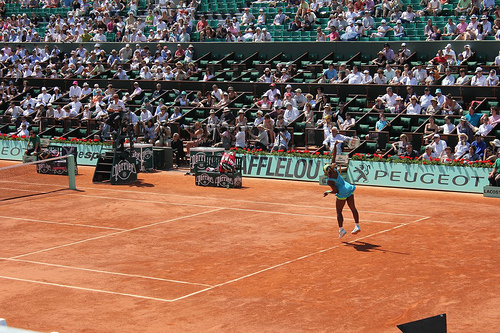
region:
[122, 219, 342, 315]
this is the playing ground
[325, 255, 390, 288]
the ground is brown in color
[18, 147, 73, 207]
this is the net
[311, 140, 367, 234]
this is a lady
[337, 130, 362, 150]
this is the racket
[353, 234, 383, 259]
this is a shadow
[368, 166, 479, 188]
this is a writing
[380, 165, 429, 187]
the writingtis is black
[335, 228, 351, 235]
this is a shoe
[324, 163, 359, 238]
tennis player in blue shirt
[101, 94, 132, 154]
referee sitting on green stand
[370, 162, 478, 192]
green sign with black letters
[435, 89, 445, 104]
man in green hat watching game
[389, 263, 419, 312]
footprints on red tennis court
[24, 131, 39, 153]
ball boy in green sitting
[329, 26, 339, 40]
man in red watching game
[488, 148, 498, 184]
guy in green sitting at side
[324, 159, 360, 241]
tennis player jumping hitting ball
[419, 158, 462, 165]
red roses on wall at side of court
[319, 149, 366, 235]
this is a tennis player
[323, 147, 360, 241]
the player is swinging the racket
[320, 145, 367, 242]
the player is on air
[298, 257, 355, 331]
the pitch is brown in color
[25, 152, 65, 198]
this is a net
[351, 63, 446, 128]
these are the spectators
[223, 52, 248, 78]
the seats are empty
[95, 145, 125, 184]
this is a staircase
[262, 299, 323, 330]
this is the ground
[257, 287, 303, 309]
the ground is sandy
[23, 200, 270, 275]
this is a tennis pitch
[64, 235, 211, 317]
the markings are white in color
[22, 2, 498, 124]
these are several spectators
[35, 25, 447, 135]
the spectators are seated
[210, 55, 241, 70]
these are empty seats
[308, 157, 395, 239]
the player has jumped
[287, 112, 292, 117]
the t-shirts are white in color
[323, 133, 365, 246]
person is playing tennis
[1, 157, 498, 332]
tennis court is brown dirt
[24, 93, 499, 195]
judges sitting in sectioned seats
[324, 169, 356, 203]
woman is wearing blue tennis outfit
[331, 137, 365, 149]
person is holding tennis racket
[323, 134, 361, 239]
person is jumping in air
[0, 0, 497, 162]
fans watch from seats in stands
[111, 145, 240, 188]
dark green advertisements for perriers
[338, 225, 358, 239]
player is wearing white shoes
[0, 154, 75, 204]
net is in middle of court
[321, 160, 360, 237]
athlete in teal tennis dress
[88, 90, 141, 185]
first official at center court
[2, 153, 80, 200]
right half of net on clay volleyball court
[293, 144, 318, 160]
a person watching the match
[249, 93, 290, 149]
a person watching the match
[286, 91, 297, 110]
a person watching the match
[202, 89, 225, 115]
a person watching the match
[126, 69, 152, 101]
a person watching the match